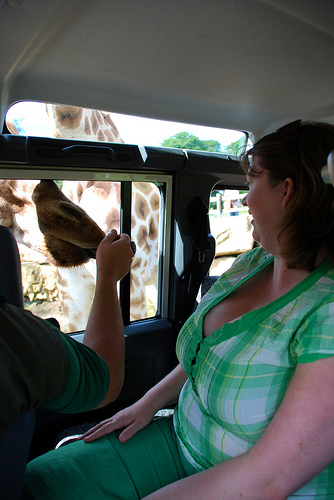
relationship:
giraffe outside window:
[0, 102, 160, 335] [1, 178, 161, 338]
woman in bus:
[25, 116, 333, 500] [1, 0, 332, 498]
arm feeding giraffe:
[4, 225, 138, 420] [0, 119, 114, 273]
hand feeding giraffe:
[95, 227, 132, 282] [0, 119, 114, 273]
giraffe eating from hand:
[0, 102, 160, 335] [93, 229, 132, 282]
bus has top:
[1, 0, 332, 498] [0, 0, 331, 148]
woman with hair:
[25, 116, 333, 500] [241, 119, 321, 275]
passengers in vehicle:
[0, 103, 333, 498] [1, 0, 332, 499]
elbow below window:
[95, 372, 125, 412] [0, 174, 174, 334]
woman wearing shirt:
[25, 116, 333, 500] [172, 246, 333, 500]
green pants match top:
[25, 413, 202, 500] [180, 263, 324, 490]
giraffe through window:
[0, 93, 171, 333] [1, 178, 161, 338]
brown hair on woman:
[242, 114, 333, 271] [25, 116, 333, 500]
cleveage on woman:
[198, 281, 265, 343] [25, 116, 333, 500]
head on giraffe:
[2, 119, 114, 275] [0, 93, 171, 333]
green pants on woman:
[25, 413, 202, 500] [25, 116, 333, 500]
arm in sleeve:
[0, 284, 126, 414] [36, 315, 108, 411]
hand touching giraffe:
[95, 227, 132, 277] [0, 93, 171, 333]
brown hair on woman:
[235, 118, 334, 276] [25, 116, 333, 500]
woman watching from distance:
[160, 116, 333, 497] [208, 180, 328, 473]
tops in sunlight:
[165, 129, 221, 149] [13, 106, 241, 152]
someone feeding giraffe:
[2, 228, 136, 496] [0, 102, 160, 335]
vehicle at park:
[1, 0, 332, 499] [8, 117, 258, 331]